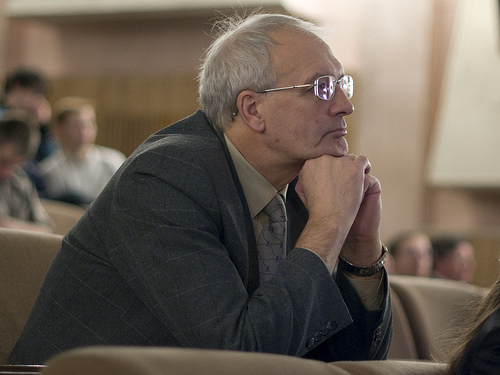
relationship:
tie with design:
[256, 190, 286, 292] [256, 228, 286, 264]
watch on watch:
[337, 243, 390, 276] [338, 241, 388, 275]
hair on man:
[198, 11, 271, 109] [11, 12, 396, 362]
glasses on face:
[257, 75, 354, 99] [238, 22, 353, 159]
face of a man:
[263, 36, 359, 175] [11, 12, 396, 362]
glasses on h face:
[257, 75, 354, 100] [263, 36, 359, 175]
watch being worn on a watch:
[340, 240, 394, 278] [337, 243, 390, 276]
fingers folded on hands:
[295, 154, 389, 235] [299, 151, 388, 232]